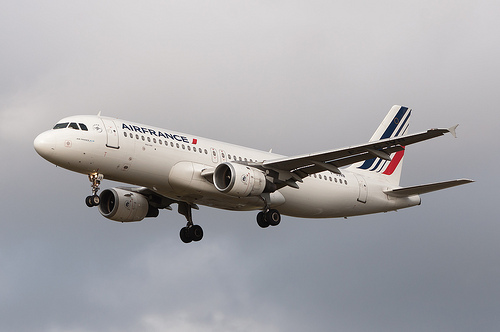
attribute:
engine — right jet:
[89, 182, 159, 230]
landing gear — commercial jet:
[175, 201, 282, 242]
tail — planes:
[344, 104, 412, 188]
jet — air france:
[29, 103, 475, 243]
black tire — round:
[261, 199, 285, 230]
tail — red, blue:
[339, 99, 445, 184]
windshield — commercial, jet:
[53, 118, 90, 135]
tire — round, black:
[177, 226, 202, 243]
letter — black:
[120, 120, 132, 132]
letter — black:
[131, 121, 143, 133]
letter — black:
[139, 124, 148, 134]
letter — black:
[159, 127, 178, 140]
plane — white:
[27, 96, 470, 232]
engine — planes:
[207, 149, 297, 208]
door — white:
[98, 116, 122, 153]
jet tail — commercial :
[350, 102, 413, 174]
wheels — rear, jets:
[246, 202, 308, 235]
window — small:
[118, 128, 192, 163]